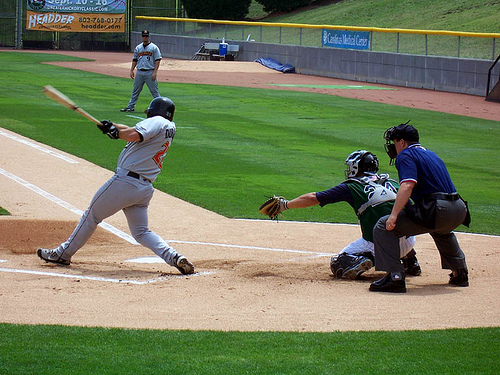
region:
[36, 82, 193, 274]
A baseball player swinging a baseball bat.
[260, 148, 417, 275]
A catcher extending for the baseball.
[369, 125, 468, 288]
An umpire watching the pitch.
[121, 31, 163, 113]
A player standing on the field.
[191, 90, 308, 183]
Lush, green grass of a baseball field.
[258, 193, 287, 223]
Glove of a catcher.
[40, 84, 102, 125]
A bat being swung.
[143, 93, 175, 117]
A protective baseball helmet.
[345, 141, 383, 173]
A catcher wearing a catcher's mask.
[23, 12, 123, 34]
An orange banner hanging up.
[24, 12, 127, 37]
Orange sign with white and black lettering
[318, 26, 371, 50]
Blue sign with white lettering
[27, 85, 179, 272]
Man swinging a baseball bat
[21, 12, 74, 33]
"Headder" in white lettering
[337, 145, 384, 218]
Man wearing catcher's protective gear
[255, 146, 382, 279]
Catcher preparing to catch baseball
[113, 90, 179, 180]
Baseball player wearing gray uniform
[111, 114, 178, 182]
Gray baseball jersey with red numbers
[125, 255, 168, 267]
Home plate of baseball diamond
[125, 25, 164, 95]
Baseball player in foul area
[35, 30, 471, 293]
Men playing baseball game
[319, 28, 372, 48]
Blue banner with white lettering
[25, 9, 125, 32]
Orange sign with white and black lettering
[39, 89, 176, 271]
Baseball player swinging a bat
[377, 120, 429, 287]
Umpire watching baseball game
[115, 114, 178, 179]
Gray baseball jersey with red lettering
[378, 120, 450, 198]
Man wearing blue shirt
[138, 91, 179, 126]
Man wearing black helmet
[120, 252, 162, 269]
Home plate of baseball diamond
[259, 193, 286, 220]
a baseball catcher's glove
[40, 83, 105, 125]
a baseball bat being swung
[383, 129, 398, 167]
side view of an umpire's face mask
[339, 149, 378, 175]
a baseball catcher's mask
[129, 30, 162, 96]
a man in a baseball jersey and sunglasses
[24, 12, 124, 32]
an orange advertisement banner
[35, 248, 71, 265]
a male baseball player's left shoe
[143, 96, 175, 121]
a dark blue batting helmet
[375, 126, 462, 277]
umpire in crouching position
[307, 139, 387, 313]
catcher on the ground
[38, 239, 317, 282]
batter's box marked in white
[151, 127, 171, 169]
number on the back of jersey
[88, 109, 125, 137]
batting gloves on hands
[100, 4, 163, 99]
player watching batter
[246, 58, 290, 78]
tarp in the corner of field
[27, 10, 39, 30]
white letter on sign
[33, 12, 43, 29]
white letter on sign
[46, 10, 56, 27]
white letter on sign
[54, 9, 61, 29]
white letter on sign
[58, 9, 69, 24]
white letter on sign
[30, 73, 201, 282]
player with a tan bat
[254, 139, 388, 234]
catcher is wearing a mitt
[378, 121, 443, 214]
umpire is wearing a helmet mask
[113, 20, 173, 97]
player standing on the field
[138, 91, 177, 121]
black helmet on the head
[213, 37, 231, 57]
water cooler on the bench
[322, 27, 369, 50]
banner on the fence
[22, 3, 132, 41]
two banners on the fence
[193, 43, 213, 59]
bench in front of the fence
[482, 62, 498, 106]
stairs next to the fence